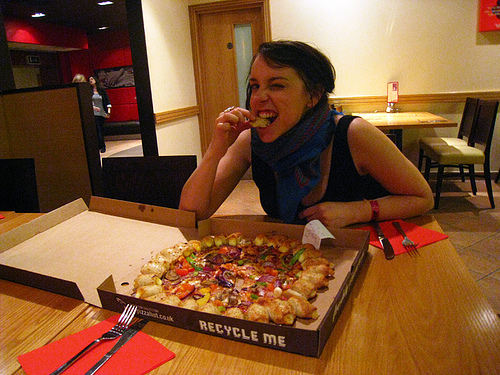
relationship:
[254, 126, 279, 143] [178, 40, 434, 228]
chin on woman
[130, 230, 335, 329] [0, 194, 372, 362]
pizza in box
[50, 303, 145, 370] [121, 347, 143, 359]
silverware on napkin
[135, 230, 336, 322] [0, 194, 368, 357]
pizza in box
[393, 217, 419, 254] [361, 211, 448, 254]
fork on red napkin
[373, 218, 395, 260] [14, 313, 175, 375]
knife on napkin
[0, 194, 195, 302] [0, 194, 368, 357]
lid on box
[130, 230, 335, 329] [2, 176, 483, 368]
pizza on table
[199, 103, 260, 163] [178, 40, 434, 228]
hand on woman